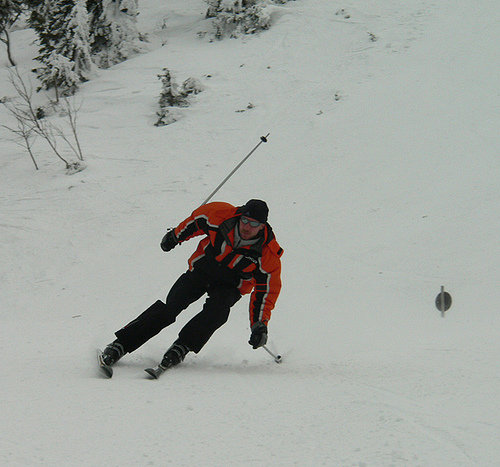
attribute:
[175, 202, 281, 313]
jacket — orange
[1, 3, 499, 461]
snow — white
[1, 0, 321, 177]
trees — bare